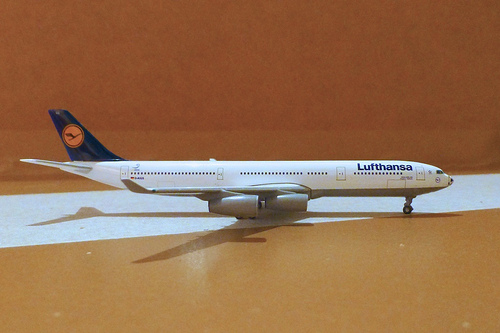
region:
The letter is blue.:
[354, 160, 364, 176]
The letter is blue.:
[362, 162, 371, 173]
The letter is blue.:
[368, 156, 377, 171]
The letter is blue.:
[372, 160, 380, 174]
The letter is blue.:
[377, 158, 387, 173]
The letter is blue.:
[384, 163, 393, 172]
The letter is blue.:
[391, 161, 401, 175]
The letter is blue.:
[398, 161, 409, 174]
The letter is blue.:
[403, 161, 414, 174]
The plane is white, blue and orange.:
[13, 93, 458, 233]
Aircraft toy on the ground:
[16, 106, 457, 228]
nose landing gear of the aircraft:
[399, 195, 414, 214]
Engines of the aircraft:
[203, 192, 310, 218]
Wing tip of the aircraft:
[119, 176, 150, 193]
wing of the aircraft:
[121, 176, 309, 196]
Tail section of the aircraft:
[16, 107, 127, 192]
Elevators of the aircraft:
[19, 155, 94, 172]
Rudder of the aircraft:
[48, 104, 119, 160]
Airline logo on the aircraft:
[60, 122, 90, 147]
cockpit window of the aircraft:
[433, 168, 443, 173]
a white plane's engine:
[196, 188, 263, 223]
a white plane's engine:
[255, 184, 310, 215]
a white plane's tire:
[398, 199, 418, 216]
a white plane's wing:
[120, 177, 304, 194]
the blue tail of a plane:
[44, 103, 130, 167]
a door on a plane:
[333, 165, 349, 180]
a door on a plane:
[414, 163, 426, 180]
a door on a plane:
[119, 162, 129, 181]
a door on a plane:
[211, 167, 226, 182]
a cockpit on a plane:
[391, 157, 457, 192]